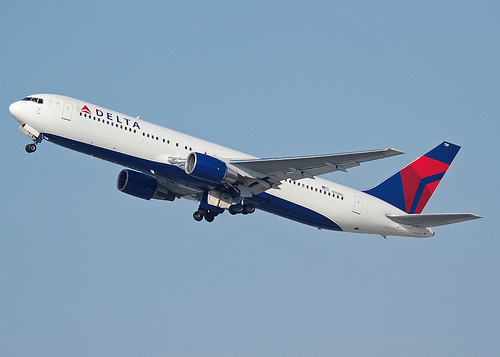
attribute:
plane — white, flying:
[9, 93, 482, 240]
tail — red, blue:
[363, 140, 481, 237]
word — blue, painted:
[96, 108, 140, 128]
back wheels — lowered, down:
[228, 202, 256, 216]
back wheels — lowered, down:
[192, 206, 217, 222]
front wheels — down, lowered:
[25, 144, 38, 153]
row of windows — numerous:
[79, 111, 346, 201]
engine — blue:
[185, 153, 248, 186]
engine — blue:
[116, 169, 175, 201]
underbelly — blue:
[41, 131, 344, 231]